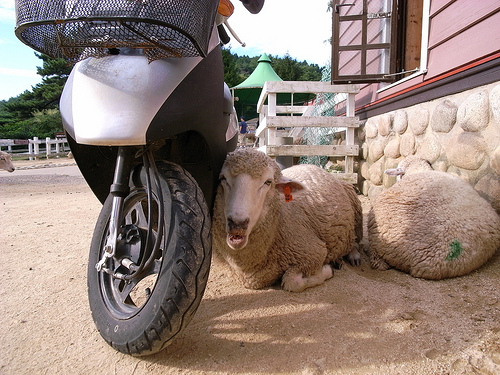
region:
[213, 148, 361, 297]
the lamb is full of wool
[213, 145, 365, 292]
the lamb's fur is off white in color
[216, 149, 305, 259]
the lamb has her mouth open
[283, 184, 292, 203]
the lamb has a tag in her ear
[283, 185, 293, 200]
the tag is red in color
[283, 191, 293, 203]
the tag has numbers on it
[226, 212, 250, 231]
the lamb's nose is black in color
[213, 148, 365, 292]
the lamb is resting on the ground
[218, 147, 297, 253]
the lamb's head is resting against the motorcycle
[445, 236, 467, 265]
the lamb's fur has a green stain on it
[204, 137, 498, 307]
Sheep are on the ground.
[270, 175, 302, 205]
A red tag is on the sheep's ear.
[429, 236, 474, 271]
A green spot is on the sheep's rear.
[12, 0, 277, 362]
A motorbike is besides the sheep.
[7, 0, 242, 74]
The motorbike has a basket.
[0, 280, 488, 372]
The ground is made of sand.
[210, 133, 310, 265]
The sheep is facing the camera.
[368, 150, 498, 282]
The sheep faces away from the camera.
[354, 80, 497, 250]
The wall is made of stones.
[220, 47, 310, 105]
A green umbrella is in the background.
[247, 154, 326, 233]
Red clip on sheeps ear.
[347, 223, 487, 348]
Green paint on sheeps but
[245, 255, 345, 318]
Sheeps leg on ground.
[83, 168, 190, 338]
Black tire with black rim.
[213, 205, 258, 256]
A sheeps open mouth.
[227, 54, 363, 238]
Home made wooden fence.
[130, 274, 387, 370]
Shadow on the ground.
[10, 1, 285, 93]
Metal basket on motorcycle.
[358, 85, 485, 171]
Stone work on side of house.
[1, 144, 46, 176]
Sheeps head entering photo.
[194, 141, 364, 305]
sheep sleeping on side of bike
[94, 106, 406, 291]
sheep sleeping on side of bike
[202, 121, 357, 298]
Goat resting against motorcycle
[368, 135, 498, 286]
Sleepy goat leaning against wall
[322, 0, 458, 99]
Open window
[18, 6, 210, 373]
Motorcycle with a metal cart in front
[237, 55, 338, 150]
People under a tent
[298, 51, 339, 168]
Mangled leftover fencing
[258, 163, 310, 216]
Sheep ear tag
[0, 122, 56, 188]
Wooden fences keeping the animals in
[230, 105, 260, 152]
Man in blue standing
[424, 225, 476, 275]
Green spot on sheep fur